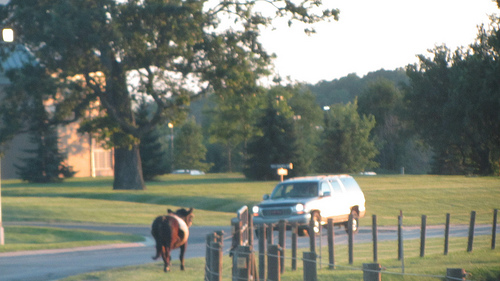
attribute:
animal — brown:
[133, 195, 198, 279]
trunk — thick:
[102, 69, 147, 189]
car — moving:
[245, 169, 367, 236]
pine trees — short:
[22, 87, 402, 184]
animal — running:
[144, 199, 204, 257]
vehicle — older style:
[249, 168, 373, 237]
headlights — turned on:
[249, 202, 306, 216]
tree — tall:
[2, 0, 340, 190]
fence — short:
[200, 190, 498, 278]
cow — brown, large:
[145, 207, 198, 273]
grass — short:
[13, 174, 490, 278]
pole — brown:
[443, 212, 450, 252]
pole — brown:
[416, 216, 426, 256]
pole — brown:
[398, 213, 402, 258]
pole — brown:
[369, 214, 377, 261]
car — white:
[247, 174, 366, 234]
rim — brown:
[351, 217, 357, 229]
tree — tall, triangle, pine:
[241, 85, 306, 182]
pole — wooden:
[489, 206, 499, 249]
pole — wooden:
[465, 210, 477, 252]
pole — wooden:
[442, 211, 452, 253]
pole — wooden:
[418, 212, 427, 256]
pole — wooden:
[396, 215, 404, 261]